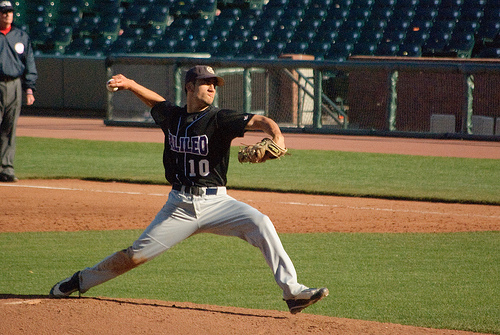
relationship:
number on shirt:
[185, 158, 209, 176] [148, 99, 254, 186]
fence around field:
[32, 54, 497, 135] [1, 104, 498, 331]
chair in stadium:
[335, 56, 345, 77] [2, 0, 499, 333]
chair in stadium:
[317, 47, 342, 64] [55, 3, 487, 65]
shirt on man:
[150, 97, 255, 186] [51, 64, 330, 314]